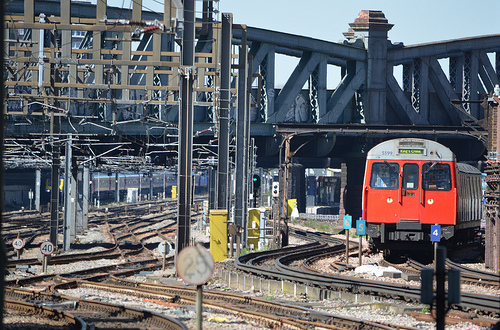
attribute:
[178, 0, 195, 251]
support — gray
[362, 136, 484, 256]
train — red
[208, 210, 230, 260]
box — yellow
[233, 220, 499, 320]
tracks — real, metal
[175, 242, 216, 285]
sign — round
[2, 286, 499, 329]
ground — gray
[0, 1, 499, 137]
bridge — cement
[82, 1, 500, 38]
sky — clear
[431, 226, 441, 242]
number — blue